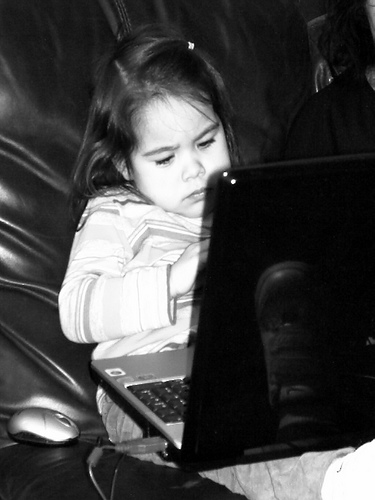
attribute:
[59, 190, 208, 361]
shirt — striped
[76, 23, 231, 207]
hair — dark, black, long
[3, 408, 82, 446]
mouse — small, wireless, silver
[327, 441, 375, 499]
shoe — white, black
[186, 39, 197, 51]
rubber band — white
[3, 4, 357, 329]
couch — black, leather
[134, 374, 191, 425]
keys — black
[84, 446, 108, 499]
usb cord — thin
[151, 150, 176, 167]
girl's eye — brown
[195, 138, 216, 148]
girl's eye — brown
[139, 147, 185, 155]
eyebrow — black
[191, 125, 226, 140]
eyebrow — black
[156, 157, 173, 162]
eyelashes — black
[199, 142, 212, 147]
eyelashes — black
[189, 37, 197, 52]
band — rubber, white